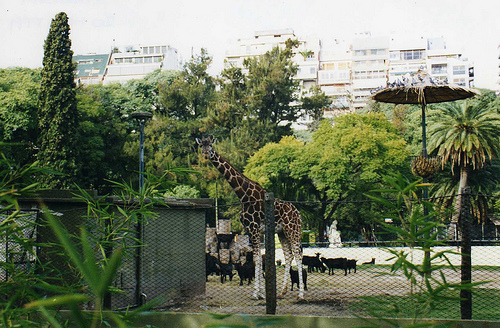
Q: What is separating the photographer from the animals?
A: A fence.